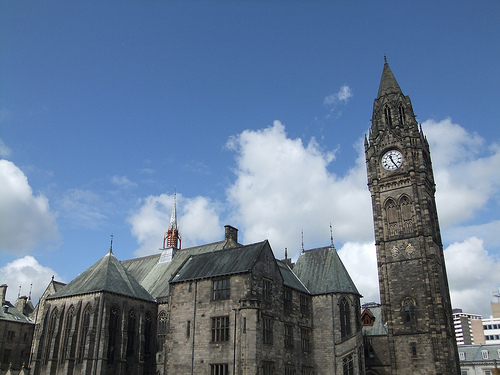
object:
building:
[363, 52, 463, 374]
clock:
[380, 148, 403, 172]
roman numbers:
[382, 162, 390, 168]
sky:
[0, 0, 499, 318]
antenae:
[328, 222, 333, 245]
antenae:
[301, 227, 303, 250]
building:
[290, 223, 367, 374]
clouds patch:
[0, 157, 62, 256]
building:
[457, 343, 500, 374]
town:
[0, 0, 499, 374]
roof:
[169, 239, 267, 282]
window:
[225, 316, 229, 328]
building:
[29, 233, 160, 374]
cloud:
[0, 159, 62, 247]